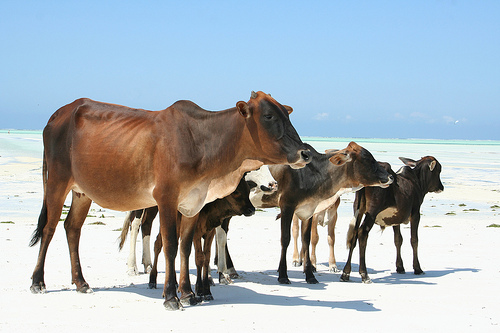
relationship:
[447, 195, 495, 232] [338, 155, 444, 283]
plants to right cows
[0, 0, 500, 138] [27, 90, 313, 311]
sky behind cow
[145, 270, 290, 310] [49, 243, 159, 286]
shadows on beach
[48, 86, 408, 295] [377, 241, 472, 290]
cows on field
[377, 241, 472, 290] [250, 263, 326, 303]
field covered with snow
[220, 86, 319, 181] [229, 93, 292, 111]
ears on head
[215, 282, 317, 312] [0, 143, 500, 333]
shadows on field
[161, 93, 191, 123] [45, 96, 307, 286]
bump on cow